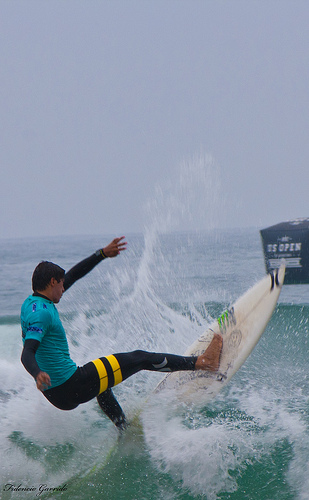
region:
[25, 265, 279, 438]
a person with the surfboard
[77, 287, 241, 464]
white foam near the surfboard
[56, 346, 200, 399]
a person wearing black color pant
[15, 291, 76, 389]
a person wearing blue color t-shirt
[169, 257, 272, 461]
white color surfboard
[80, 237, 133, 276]
a person lifting his hand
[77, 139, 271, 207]
sky with clouds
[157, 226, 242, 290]
small waves in the sea water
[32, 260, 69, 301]
a person's head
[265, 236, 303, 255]
something written in white color text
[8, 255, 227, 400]
A man sketing in the sea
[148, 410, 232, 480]
A white splush of water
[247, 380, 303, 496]
A white splush of water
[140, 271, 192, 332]
A white splush of water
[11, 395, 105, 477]
A white splush of water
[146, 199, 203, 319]
A white splush of water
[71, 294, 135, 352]
A white splush of water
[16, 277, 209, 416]
A fitthing swim suit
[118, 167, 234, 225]
A grey sky background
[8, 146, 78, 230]
A grey sky background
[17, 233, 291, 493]
man on white surfboard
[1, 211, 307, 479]
waves under man with surfboard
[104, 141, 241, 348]
water splashed up in front of man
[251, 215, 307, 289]
blue box with us open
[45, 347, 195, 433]
black pants with two yellow stripes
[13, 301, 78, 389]
teal blue wet shirt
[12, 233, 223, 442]
man has on wet suit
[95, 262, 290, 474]
two small black stripes on white surfboard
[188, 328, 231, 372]
man's bare foot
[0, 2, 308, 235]
clear blue sky over sufer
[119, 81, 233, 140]
dark clouds in the sky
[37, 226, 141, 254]
rough surf in the ocean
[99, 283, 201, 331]
large white waves breaking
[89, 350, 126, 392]
large yellow lines around pants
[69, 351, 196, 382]
man wearing blue stretch pants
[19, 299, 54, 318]
symbols on light blue shirt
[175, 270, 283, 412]
white surfboard in water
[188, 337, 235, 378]
man's foot on surf board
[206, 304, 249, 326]
green color on surf board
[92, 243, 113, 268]
black watch on man's hand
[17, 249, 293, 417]
Man on a surf board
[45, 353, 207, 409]
man wearing black pants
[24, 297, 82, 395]
man wearing a blue shirt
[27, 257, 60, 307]
man with black hair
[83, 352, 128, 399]
yellow stripe on pants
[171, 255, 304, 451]
man on a white surfboard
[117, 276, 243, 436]
water spraying in the air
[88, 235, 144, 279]
man with his hand out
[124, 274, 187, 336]
waves crashing in the ocean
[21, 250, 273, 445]
man falling on a surfboard